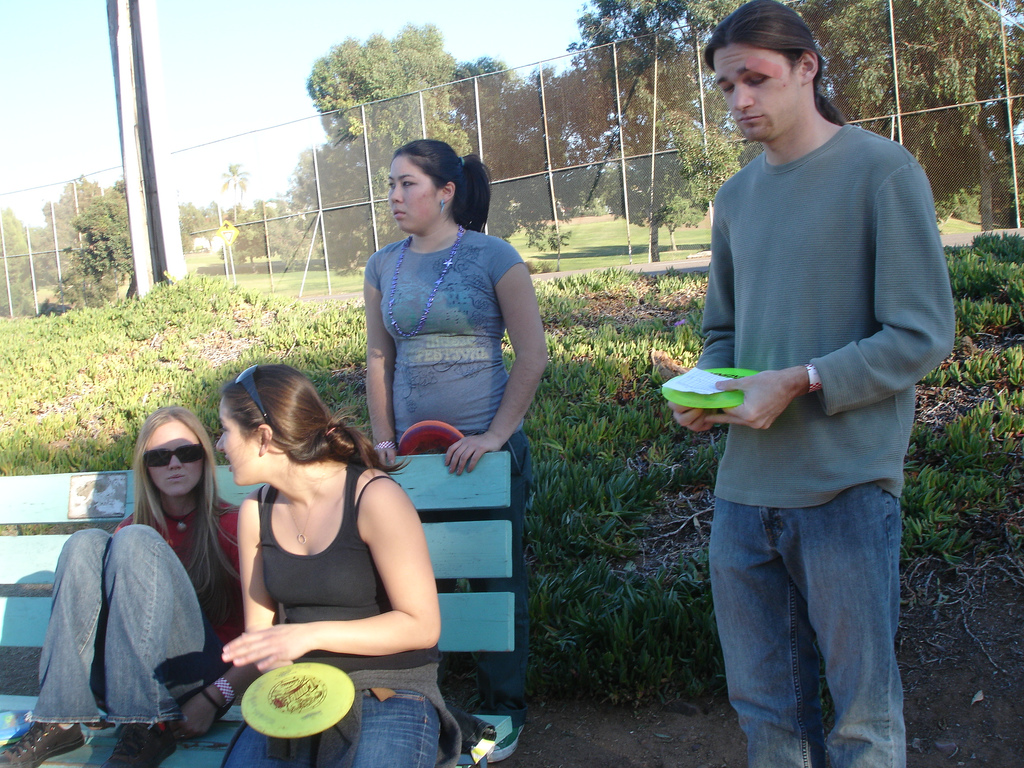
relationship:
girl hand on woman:
[439, 433, 504, 473] [362, 137, 543, 763]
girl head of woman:
[128, 404, 206, 523] [2, 405, 240, 767]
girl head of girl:
[215, 360, 321, 485] [217, 357, 449, 757]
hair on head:
[394, 132, 492, 232] [379, 141, 494, 232]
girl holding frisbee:
[204, 371, 464, 760] [239, 658, 353, 739]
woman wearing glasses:
[2, 405, 240, 766] [145, 439, 200, 471]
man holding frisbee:
[667, 0, 958, 766] [659, 357, 765, 412]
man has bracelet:
[667, 0, 958, 766] [806, 361, 820, 390]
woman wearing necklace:
[363, 137, 547, 766] [384, 225, 464, 342]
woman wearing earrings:
[363, 137, 547, 766] [442, 197, 446, 213]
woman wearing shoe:
[2, 405, 240, 766] [106, 718, 182, 766]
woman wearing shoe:
[2, 405, 240, 766] [2, 715, 88, 766]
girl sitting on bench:
[217, 366, 444, 768] [0, 447, 519, 765]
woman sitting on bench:
[2, 405, 240, 766] [0, 447, 519, 765]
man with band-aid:
[667, 0, 958, 766] [748, 55, 780, 81]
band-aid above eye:
[748, 55, 780, 81] [745, 73, 768, 86]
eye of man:
[745, 73, 768, 86] [667, 0, 958, 766]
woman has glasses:
[2, 405, 240, 766] [143, 444, 201, 466]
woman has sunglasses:
[2, 405, 240, 766] [233, 364, 275, 422]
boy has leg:
[666, 0, 957, 766] [707, 496, 815, 766]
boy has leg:
[666, 0, 957, 766] [782, 482, 906, 765]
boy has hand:
[666, 0, 957, 766] [703, 365, 795, 432]